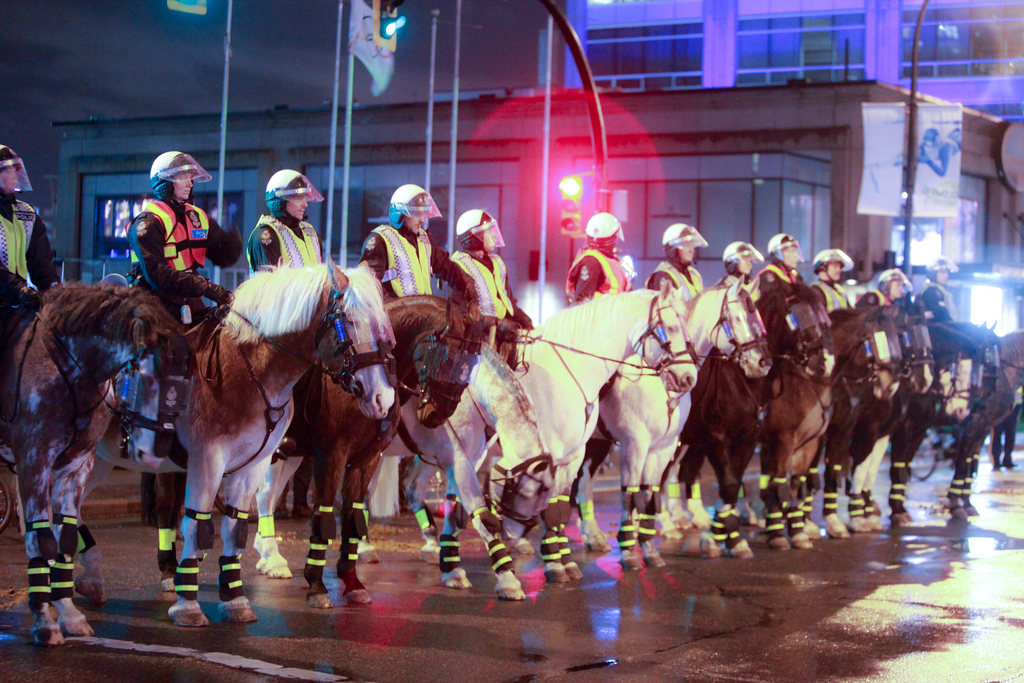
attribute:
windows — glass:
[554, 41, 693, 89]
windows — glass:
[737, 22, 815, 90]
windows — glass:
[759, 41, 870, 117]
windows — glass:
[666, 41, 719, 89]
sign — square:
[833, 100, 993, 247]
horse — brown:
[754, 268, 843, 558]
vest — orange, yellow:
[140, 198, 225, 283]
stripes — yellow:
[374, 224, 444, 298]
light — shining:
[557, 157, 601, 209]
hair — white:
[218, 254, 396, 350]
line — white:
[102, 622, 336, 677]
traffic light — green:
[378, 0, 422, 61]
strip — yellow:
[19, 550, 95, 617]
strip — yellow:
[45, 559, 85, 605]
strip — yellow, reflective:
[51, 508, 82, 532]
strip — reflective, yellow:
[49, 551, 78, 571]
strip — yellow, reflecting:
[176, 558, 200, 578]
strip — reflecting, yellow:
[172, 577, 201, 601]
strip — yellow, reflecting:
[300, 536, 333, 554]